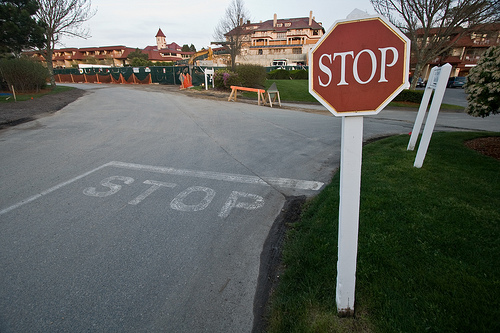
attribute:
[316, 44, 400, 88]
stop — white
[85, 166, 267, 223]
stop — white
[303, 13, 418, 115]
sign — red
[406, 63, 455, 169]
sign — white, framed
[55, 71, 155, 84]
netting — orange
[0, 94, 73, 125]
area — muddy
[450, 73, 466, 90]
car — parked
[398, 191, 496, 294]
lawn — green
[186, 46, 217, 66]
vehicle — yellow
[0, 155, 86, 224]
line — white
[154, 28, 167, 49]
tower — tan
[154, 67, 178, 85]
gate — green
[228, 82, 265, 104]
sawhorse — orange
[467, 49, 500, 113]
tree — blooming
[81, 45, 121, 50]
roof — red